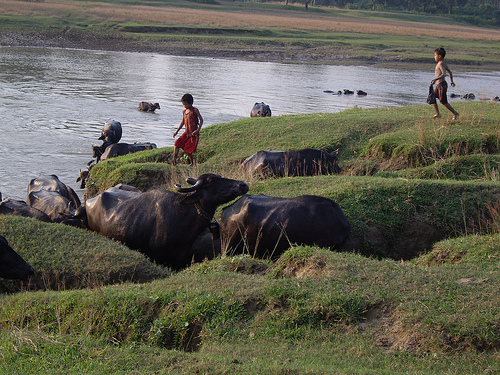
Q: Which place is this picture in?
A: It is at the lake.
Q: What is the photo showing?
A: It is showing a lake.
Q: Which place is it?
A: It is a lake.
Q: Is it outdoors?
A: Yes, it is outdoors.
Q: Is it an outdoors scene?
A: Yes, it is outdoors.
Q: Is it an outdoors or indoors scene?
A: It is outdoors.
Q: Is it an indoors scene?
A: No, it is outdoors.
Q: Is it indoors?
A: No, it is outdoors.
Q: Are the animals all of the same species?
A: No, there are both hippoes and cows.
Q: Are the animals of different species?
A: Yes, they are hippoes and cows.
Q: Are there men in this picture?
A: No, there are no men.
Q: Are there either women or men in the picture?
A: No, there are no men or women.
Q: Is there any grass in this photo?
A: Yes, there is grass.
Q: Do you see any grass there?
A: Yes, there is grass.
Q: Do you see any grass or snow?
A: Yes, there is grass.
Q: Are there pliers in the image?
A: No, there are no pliers.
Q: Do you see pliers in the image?
A: No, there are no pliers.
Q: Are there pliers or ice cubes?
A: No, there are no pliers or ice cubes.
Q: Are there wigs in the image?
A: No, there are no wigs.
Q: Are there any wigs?
A: No, there are no wigs.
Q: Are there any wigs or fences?
A: No, there are no wigs or fences.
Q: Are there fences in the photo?
A: No, there are no fences.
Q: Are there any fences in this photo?
A: No, there are no fences.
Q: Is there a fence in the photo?
A: No, there are no fences.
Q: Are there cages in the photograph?
A: No, there are no cages.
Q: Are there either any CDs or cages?
A: No, there are no cages or cds.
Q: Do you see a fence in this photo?
A: No, there are no fences.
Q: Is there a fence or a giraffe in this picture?
A: No, there are no fences or giraffes.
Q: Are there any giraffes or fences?
A: No, there are no fences or giraffes.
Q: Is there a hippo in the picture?
A: Yes, there is a hippo.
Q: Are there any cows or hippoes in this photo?
A: Yes, there is a hippo.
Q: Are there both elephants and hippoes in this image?
A: No, there is a hippo but no elephants.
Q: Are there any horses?
A: No, there are no horses.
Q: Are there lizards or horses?
A: No, there are no horses or lizards.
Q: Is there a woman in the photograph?
A: No, there are no women.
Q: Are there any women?
A: No, there are no women.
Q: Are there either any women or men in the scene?
A: No, there are no women or men.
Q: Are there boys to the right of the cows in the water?
A: Yes, there is a boy to the right of the cows.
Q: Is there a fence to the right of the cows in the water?
A: No, there is a boy to the right of the cows.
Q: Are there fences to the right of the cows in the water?
A: No, there is a boy to the right of the cows.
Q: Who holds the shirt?
A: The boy holds the shirt.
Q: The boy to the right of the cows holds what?
A: The boy holds the shirt.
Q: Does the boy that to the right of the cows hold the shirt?
A: Yes, the boy holds the shirt.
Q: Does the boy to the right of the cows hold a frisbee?
A: No, the boy holds the shirt.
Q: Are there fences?
A: No, there are no fences.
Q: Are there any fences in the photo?
A: No, there are no fences.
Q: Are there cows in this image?
A: Yes, there are cows.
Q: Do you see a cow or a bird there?
A: Yes, there are cows.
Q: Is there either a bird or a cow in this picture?
A: Yes, there are cows.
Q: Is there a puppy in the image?
A: No, there are no puppys.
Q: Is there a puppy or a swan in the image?
A: No, there are no puppys or swans.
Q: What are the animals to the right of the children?
A: The animals are cows.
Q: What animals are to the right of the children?
A: The animals are cows.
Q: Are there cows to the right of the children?
A: Yes, there are cows to the right of the children.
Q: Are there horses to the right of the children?
A: No, there are cows to the right of the children.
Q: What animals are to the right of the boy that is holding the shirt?
A: The animals are cows.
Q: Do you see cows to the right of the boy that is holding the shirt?
A: Yes, there are cows to the right of the boy.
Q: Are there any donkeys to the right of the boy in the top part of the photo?
A: No, there are cows to the right of the boy.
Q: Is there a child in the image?
A: Yes, there are children.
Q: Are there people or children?
A: Yes, there are children.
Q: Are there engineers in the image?
A: No, there are no engineers.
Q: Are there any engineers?
A: No, there are no engineers.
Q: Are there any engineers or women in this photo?
A: No, there are no engineers or women.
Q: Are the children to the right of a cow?
A: Yes, the children are to the right of a cow.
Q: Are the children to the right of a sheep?
A: No, the children are to the right of a cow.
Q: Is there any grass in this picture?
A: Yes, there is grass.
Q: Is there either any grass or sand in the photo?
A: Yes, there is grass.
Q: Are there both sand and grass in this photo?
A: No, there is grass but no sand.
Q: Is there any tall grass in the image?
A: Yes, there is tall grass.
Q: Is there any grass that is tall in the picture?
A: Yes, there is tall grass.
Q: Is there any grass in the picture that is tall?
A: Yes, there is grass that is tall.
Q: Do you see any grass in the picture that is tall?
A: Yes, there is grass that is tall.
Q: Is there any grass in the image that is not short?
A: Yes, there is tall grass.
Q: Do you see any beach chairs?
A: No, there are no beach chairs.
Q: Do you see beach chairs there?
A: No, there are no beach chairs.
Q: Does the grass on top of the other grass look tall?
A: Yes, the grass is tall.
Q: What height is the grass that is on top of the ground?
A: The grass is tall.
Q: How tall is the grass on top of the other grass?
A: The grass is tall.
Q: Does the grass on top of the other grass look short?
A: No, the grass is tall.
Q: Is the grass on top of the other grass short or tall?
A: The grass is tall.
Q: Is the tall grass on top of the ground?
A: Yes, the grass is on top of the ground.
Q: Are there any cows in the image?
A: Yes, there is a cow.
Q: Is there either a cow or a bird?
A: Yes, there is a cow.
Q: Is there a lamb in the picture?
A: No, there are no lambs.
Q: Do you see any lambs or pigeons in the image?
A: No, there are no lambs or pigeons.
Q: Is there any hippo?
A: Yes, there is a hippo.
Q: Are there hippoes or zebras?
A: Yes, there is a hippo.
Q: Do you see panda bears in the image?
A: No, there are no panda bears.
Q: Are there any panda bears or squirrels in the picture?
A: No, there are no panda bears or squirrels.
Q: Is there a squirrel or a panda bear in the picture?
A: No, there are no panda bears or squirrels.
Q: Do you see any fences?
A: No, there are no fences.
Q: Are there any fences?
A: No, there are no fences.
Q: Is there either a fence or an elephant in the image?
A: No, there are no fences or elephants.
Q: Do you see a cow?
A: Yes, there is a cow.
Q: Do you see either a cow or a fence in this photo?
A: Yes, there is a cow.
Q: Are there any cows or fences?
A: Yes, there is a cow.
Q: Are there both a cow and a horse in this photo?
A: No, there is a cow but no horses.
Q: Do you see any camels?
A: No, there are no camels.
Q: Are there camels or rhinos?
A: No, there are no camels or rhinos.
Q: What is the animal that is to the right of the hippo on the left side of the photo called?
A: The animal is a cow.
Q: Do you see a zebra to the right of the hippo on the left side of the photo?
A: No, there is a cow to the right of the hippo.